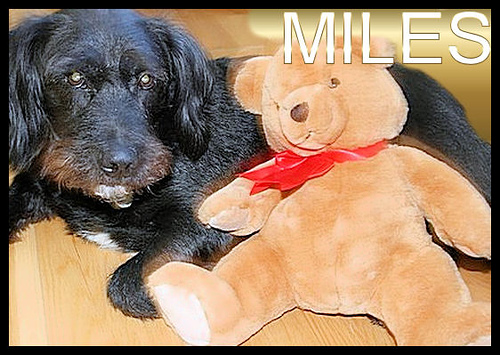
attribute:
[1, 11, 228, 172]
ears — floppy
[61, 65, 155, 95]
eyes — small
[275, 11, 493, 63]
miles — capitalized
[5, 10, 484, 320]
dog — black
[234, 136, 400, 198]
ribbon — red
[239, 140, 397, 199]
ribbon — red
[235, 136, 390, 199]
band — red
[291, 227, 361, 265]
fur — brown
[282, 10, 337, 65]
letter — white, print style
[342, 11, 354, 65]
letter — print style, white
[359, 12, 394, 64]
letter — white, print style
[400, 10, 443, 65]
letter — print style, white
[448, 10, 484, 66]
letter — white, print style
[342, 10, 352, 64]
letter — print style, white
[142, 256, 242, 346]
paw — brown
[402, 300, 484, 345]
paw — brown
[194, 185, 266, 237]
paw — brown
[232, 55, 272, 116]
ear — brown